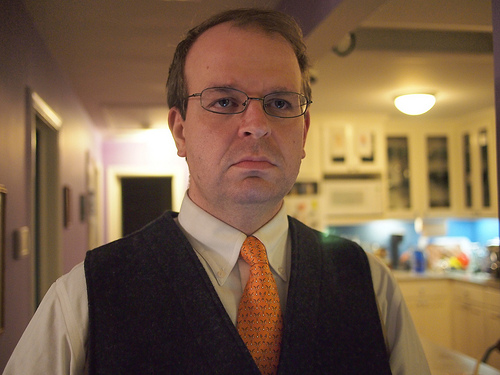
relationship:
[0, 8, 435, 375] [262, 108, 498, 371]
guy near kitchen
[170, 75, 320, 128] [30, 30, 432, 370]
glasses on man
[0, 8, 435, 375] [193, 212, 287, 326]
guy with shirt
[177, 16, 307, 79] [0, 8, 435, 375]
hairline of guy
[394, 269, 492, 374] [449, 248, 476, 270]
kitchen counterop with item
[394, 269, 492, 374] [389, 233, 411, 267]
kitchen counterop with item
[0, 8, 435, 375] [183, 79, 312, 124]
guy wearing glasses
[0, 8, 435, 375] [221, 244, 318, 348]
guy wearing tie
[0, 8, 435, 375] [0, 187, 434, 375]
guy wearing collard shirt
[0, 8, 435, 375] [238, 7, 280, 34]
guy with hair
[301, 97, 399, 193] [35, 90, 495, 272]
picture on wall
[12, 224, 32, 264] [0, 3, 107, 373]
switch on wall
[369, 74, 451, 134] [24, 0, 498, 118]
light on ceiling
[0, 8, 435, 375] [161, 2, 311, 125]
guy with hair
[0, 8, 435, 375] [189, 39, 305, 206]
guy with face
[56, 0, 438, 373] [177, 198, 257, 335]
guy with collard shirt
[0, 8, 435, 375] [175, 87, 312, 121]
guy wearing glasses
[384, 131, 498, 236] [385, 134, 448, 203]
cabinets has glass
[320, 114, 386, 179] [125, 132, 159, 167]
cabinets on wall